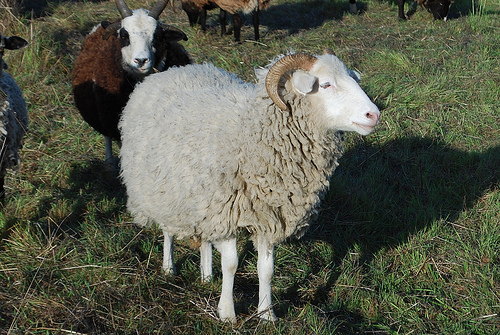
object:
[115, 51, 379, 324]
sheep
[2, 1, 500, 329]
pasture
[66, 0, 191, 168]
sheep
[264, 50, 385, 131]
head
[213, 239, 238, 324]
leg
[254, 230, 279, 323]
leg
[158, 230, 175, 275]
leg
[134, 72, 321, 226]
fur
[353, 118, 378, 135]
mouth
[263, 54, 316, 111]
horn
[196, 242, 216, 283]
leg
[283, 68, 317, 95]
ear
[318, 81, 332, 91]
eye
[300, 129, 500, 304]
shadow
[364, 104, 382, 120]
nose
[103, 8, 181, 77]
head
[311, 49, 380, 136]
face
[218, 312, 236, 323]
hoof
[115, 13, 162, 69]
face